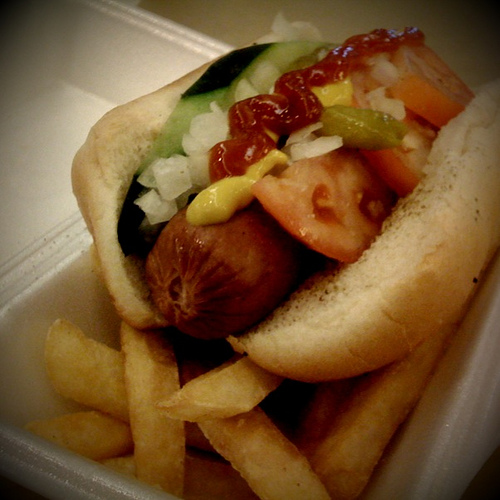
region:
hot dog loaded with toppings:
[67, 13, 499, 383]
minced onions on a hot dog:
[131, 97, 231, 225]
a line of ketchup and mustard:
[188, 24, 428, 223]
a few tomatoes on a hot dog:
[253, 37, 477, 266]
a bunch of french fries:
[22, 293, 475, 497]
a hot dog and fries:
[31, 22, 499, 493]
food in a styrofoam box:
[1, 1, 499, 496]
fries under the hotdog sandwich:
[45, 142, 347, 475]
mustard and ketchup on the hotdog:
[187, 96, 292, 233]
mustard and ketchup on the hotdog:
[165, 129, 295, 381]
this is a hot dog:
[2, 15, 497, 497]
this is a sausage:
[128, 205, 290, 336]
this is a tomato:
[253, 154, 376, 254]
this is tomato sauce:
[273, 49, 333, 122]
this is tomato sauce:
[332, 8, 410, 66]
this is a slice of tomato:
[369, 105, 431, 190]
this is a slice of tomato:
[377, 10, 497, 127]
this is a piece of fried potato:
[100, 312, 205, 496]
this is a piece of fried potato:
[178, 354, 339, 497]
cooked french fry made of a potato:
[150, 347, 286, 433]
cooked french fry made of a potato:
[112, 311, 187, 498]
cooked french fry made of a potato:
[39, 310, 129, 420]